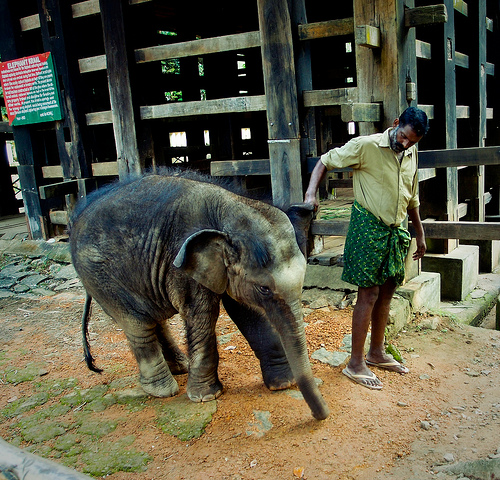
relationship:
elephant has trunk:
[68, 174, 331, 423] [256, 299, 328, 423]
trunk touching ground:
[256, 299, 328, 423] [0, 232, 499, 478]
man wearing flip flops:
[302, 109, 437, 391] [341, 352, 411, 394]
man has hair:
[302, 109, 437, 391] [399, 104, 431, 139]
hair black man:
[399, 104, 431, 139] [302, 109, 437, 391]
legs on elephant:
[177, 299, 298, 404] [68, 174, 331, 423]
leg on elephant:
[168, 282, 226, 402] [68, 174, 331, 423]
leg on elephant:
[223, 294, 293, 389] [68, 174, 331, 423]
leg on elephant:
[90, 278, 178, 397] [68, 174, 331, 423]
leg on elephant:
[150, 319, 190, 376] [68, 174, 331, 423]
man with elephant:
[47, 97, 453, 434] [68, 174, 331, 423]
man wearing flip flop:
[302, 109, 437, 391] [366, 352, 408, 373]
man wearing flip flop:
[302, 109, 437, 391] [338, 362, 383, 392]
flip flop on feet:
[366, 352, 408, 373] [345, 351, 410, 387]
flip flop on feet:
[338, 362, 383, 392] [345, 351, 410, 387]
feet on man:
[345, 351, 410, 387] [302, 109, 437, 391]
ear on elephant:
[174, 232, 237, 295] [68, 174, 331, 423]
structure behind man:
[2, 0, 498, 298] [302, 109, 437, 391]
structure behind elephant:
[2, 0, 498, 298] [68, 174, 331, 423]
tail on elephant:
[72, 286, 105, 381] [68, 174, 331, 423]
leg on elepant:
[90, 278, 178, 397] [29, 116, 361, 422]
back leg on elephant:
[124, 320, 177, 411] [68, 174, 331, 423]